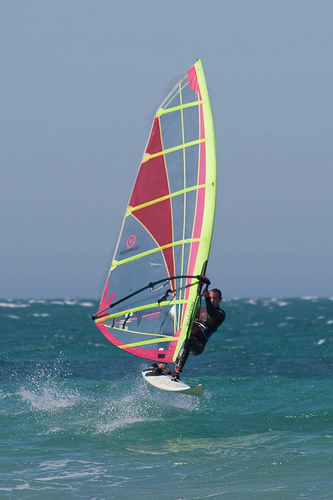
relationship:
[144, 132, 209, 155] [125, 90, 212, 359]
strip on sail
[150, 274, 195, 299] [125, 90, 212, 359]
handle on sail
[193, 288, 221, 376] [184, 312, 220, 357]
man wearing wet suit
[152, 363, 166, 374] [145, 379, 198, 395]
pole connected to board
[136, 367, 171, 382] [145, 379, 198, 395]
holes on board